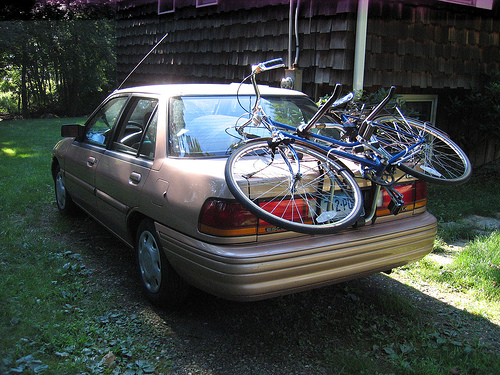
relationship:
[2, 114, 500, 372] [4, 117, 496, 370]
ground has a shady area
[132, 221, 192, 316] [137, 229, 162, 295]
tire has a silver rim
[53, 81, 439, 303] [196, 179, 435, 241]
car has red taillights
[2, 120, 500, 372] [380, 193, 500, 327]
grass has a sun lit patch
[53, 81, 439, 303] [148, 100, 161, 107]
car has a rear view mirror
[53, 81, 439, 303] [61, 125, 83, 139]
car has a side mirror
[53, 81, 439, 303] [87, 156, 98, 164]
car has a tan door handle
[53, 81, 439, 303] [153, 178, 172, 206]
car has a gas tank door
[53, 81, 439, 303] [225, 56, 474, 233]
car has on it a blue bike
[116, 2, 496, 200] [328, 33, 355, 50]
building has brown wood siding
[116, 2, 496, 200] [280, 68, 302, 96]
building has a utility meter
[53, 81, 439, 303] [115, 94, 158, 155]
car has an open window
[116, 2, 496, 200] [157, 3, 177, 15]
building has a window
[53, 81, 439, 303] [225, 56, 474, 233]
car hauling a blue bike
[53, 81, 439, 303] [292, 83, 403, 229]
car has a bike rack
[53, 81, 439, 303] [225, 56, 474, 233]
car carrying a blue bike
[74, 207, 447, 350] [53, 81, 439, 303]
gravel under car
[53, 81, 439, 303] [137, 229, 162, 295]
car has a silver rim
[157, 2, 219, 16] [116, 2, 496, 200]
windows on side of building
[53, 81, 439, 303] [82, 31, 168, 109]
car has an antenna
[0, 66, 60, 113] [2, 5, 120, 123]
meadow located past trees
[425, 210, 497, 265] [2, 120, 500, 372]
sidewalk has growing grass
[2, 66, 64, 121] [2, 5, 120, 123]
sunlight shining through trees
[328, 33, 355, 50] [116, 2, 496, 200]
brown wood siding on building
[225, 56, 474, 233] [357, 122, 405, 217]
bike has two foot pedals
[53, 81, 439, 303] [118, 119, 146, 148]
car has a steering wheel